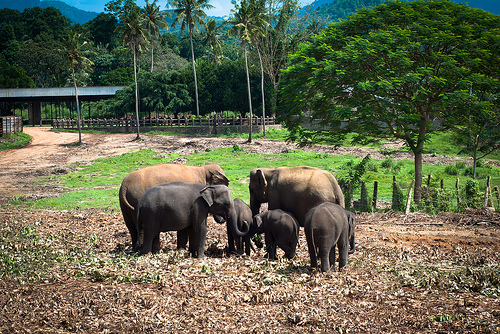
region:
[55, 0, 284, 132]
Palm trees in background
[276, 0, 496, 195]
green shade tree behind elephants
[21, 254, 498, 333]
dead foliage on ground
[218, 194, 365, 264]
3 brown baby elephants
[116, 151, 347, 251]
3 brown adult elephants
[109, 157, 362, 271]
group of elephants in pasture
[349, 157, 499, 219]
old wooden fencing needing repair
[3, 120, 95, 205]
dirt road leading to enclosure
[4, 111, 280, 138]
wooden fencing in front of enclosure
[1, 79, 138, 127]
roofed enclosure behind fence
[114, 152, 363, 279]
the elephants are a family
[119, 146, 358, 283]
the elephants have trunks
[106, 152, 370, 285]
the elephants are gathered together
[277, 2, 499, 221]
the tree is green and leafy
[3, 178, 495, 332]
the grass is dry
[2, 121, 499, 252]
the grass is green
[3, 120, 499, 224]
the dirt is brown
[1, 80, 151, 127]
the bridge is in the distance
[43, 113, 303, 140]
the fence is concrete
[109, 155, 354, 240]
the two elephants in the back are brown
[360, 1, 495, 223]
tree with bright green leaves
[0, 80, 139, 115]
a outside deck roof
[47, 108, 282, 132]
wooden picket fencing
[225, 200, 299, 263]
two baby elephants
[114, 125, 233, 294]
two large elephants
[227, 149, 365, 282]
a family of elephants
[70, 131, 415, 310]
a large group of elephants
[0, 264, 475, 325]
grown covered in brown grass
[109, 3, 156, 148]
a green palm tree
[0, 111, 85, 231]
a dirt path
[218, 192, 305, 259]
two baby elephants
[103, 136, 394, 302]
a group of elephants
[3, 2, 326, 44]
the sky is blue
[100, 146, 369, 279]
the elephants are gray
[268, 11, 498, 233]
the tree is green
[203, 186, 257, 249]
the elephant's trunk is curled up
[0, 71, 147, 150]
a pavilion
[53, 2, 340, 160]
the trees are tall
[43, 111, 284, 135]
the fence is brown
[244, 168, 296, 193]
adult brown elephant with family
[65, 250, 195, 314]
mulch that elephants are on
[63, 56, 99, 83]
distant palm trees in background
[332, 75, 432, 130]
tall tree near animals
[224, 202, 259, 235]
trunk of male elephant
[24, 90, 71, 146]
trail that animals can walk along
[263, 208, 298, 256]
dark baby black elephant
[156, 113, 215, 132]
fence containing some sort of animal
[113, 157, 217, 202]
large elephant with family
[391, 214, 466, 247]
more mulch around animals